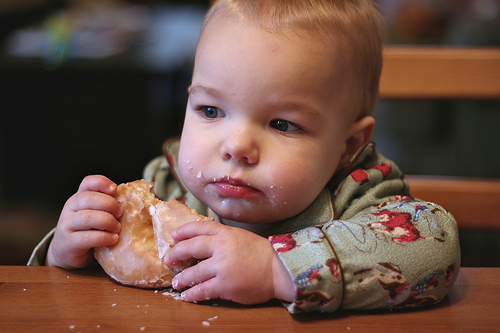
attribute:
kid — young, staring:
[40, 2, 463, 317]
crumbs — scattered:
[110, 289, 214, 330]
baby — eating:
[118, 21, 442, 271]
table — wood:
[0, 265, 500, 330]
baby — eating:
[48, 30, 449, 312]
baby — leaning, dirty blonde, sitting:
[27, 0, 461, 315]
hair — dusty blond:
[193, 1, 384, 118]